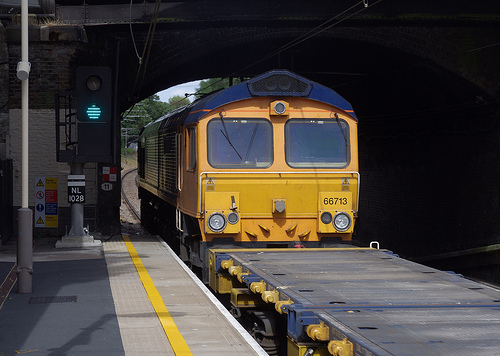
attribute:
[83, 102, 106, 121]
light — green, for traffic, blue, circular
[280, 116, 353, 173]
window — square, present, large, rectangular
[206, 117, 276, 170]
window — square, large, rectangular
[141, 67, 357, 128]
top of train — blue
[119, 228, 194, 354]
line — yellow, wide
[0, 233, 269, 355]
floor — at train station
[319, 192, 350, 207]
numbers — 67713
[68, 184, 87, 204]
letters — white, nl8028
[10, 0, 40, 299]
post — white, tall, metal, large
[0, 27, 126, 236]
wall — made of bricks, dome shaped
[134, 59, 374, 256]
train — yellow, blue, large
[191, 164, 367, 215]
handle — metal, large, thin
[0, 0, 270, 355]
platform — lined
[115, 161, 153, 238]
train tracks — curved, black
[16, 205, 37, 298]
concrete base — gray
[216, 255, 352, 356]
bolts — large, silver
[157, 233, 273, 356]
edge — white